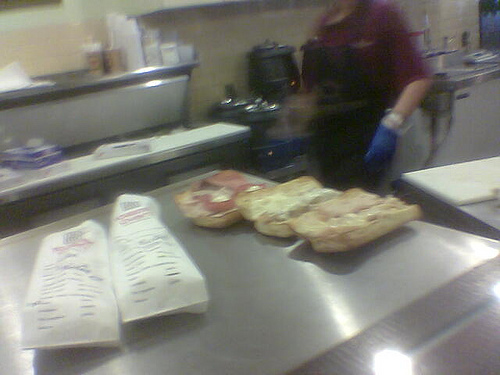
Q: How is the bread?
A: Toasted.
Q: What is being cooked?
A: Sandwixch.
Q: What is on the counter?
A: Food.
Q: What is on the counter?
A: A bag.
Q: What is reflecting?
A: Light.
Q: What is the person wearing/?
A: Apron.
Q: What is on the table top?
A: Sandwiches.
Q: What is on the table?
A: Food.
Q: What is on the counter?
A: Sandwiches.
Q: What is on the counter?
A: Three sandwiches.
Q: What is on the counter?
A: Three sandwiches.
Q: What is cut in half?
A: Three breads.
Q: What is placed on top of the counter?
A: French bread that is toasted.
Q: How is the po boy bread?
A: It is toasted.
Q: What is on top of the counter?
A: Sandwiches.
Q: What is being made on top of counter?
A: Three sandwiches.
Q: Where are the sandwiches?
A: On a table.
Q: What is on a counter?
A: Sandwiches.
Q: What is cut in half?
A: Sandwich bread.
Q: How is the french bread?
A: It is cut in half.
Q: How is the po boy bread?
A: It is cut in half.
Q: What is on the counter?
A: Food.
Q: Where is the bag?
A: The counter.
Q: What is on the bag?
A: Writing.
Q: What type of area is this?
A: Food preparation.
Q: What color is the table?
A: Silver.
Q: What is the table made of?
A: Metal.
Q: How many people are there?
A: One.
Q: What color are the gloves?
A: Blue.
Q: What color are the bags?
A: White.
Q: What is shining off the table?
A: Lights.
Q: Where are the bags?
A: On the table.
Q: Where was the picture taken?
A: In a kitchen.